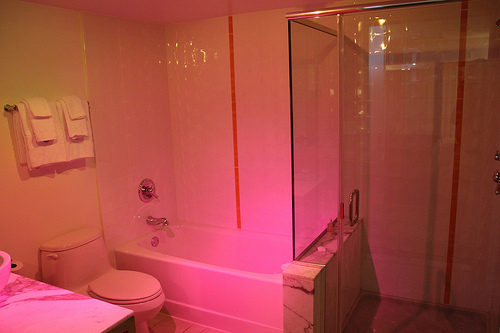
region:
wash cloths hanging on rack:
[22, 98, 58, 143]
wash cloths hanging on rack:
[57, 97, 92, 137]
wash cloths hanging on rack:
[16, 98, 99, 140]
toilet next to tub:
[39, 230, 175, 309]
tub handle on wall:
[137, 176, 157, 201]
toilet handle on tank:
[44, 250, 66, 259]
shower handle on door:
[338, 193, 359, 234]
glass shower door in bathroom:
[339, 2, 498, 329]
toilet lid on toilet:
[95, 270, 166, 302]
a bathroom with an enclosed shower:
[4, 3, 497, 331]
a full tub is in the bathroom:
[111, 213, 310, 331]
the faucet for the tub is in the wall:
[140, 210, 175, 236]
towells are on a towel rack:
[5, 90, 100, 177]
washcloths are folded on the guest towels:
[25, 91, 92, 146]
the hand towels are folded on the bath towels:
[19, 120, 95, 174]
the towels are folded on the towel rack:
[13, 95, 99, 177]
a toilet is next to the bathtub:
[37, 223, 166, 328]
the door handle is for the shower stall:
[333, 178, 370, 243]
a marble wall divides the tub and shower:
[281, 216, 364, 331]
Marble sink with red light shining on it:
[3, 242, 137, 331]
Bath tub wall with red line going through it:
[74, 40, 318, 331]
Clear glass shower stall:
[281, 38, 496, 328]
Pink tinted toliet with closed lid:
[28, 225, 169, 328]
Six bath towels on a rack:
[6, 93, 94, 177]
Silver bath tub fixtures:
[126, 169, 173, 236]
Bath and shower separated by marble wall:
[71, 6, 493, 331]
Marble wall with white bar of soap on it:
[280, 209, 375, 331]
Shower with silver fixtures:
[274, 6, 499, 328]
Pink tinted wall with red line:
[74, 5, 339, 240]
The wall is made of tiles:
[126, 50, 209, 148]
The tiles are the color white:
[114, 70, 219, 150]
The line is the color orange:
[220, 15, 247, 235]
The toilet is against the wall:
[39, 226, 181, 329]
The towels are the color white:
[4, 88, 101, 175]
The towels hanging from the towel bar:
[6, 89, 96, 164]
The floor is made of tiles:
[152, 315, 232, 331]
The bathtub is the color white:
[122, 213, 289, 327]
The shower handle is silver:
[129, 177, 166, 206]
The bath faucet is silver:
[144, 208, 173, 230]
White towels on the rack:
[7, 98, 96, 170]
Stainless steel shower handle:
[135, 178, 162, 204]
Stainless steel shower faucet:
[145, 213, 173, 230]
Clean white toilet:
[42, 229, 172, 331]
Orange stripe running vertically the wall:
[221, 13, 249, 229]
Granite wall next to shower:
[269, 205, 379, 331]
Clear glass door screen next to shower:
[286, 2, 498, 331]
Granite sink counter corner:
[0, 259, 138, 331]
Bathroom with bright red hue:
[2, 3, 492, 328]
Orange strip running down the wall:
[436, 3, 471, 307]